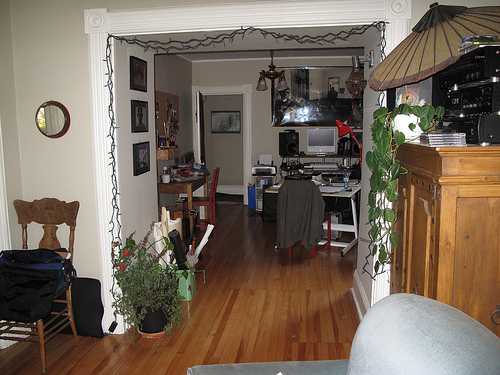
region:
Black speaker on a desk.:
[277, 129, 299, 159]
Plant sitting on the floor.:
[111, 222, 190, 337]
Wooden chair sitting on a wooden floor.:
[0, 198, 80, 372]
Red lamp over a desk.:
[335, 120, 363, 160]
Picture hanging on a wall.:
[208, 109, 242, 134]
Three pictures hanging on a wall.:
[130, 55, 150, 175]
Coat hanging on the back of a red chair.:
[270, 175, 321, 250]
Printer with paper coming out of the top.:
[250, 150, 276, 175]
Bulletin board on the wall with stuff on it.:
[152, 86, 178, 141]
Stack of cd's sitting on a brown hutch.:
[417, 131, 469, 149]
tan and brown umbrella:
[395, 4, 498, 101]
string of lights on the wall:
[108, 0, 409, 253]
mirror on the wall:
[28, 92, 99, 150]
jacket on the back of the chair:
[264, 177, 354, 267]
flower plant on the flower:
[110, 250, 202, 365]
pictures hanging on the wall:
[116, 56, 156, 191]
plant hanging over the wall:
[370, 104, 405, 287]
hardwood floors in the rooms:
[216, 248, 348, 352]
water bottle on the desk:
[333, 167, 355, 193]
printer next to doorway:
[252, 150, 280, 180]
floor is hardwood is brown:
[216, 243, 328, 342]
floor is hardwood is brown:
[246, 258, 314, 334]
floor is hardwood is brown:
[205, 293, 312, 343]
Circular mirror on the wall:
[33, 98, 69, 138]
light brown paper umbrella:
[362, 1, 497, 92]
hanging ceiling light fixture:
[255, 50, 290, 95]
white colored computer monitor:
[305, 126, 336, 156]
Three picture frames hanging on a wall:
[126, 53, 151, 176]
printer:
[250, 151, 276, 177]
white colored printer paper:
[260, 153, 271, 164]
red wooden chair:
[190, 166, 218, 226]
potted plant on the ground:
[111, 231, 177, 337]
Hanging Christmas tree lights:
[107, 17, 387, 336]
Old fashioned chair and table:
[5, 173, 106, 366]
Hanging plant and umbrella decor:
[356, 5, 496, 172]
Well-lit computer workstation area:
[269, 108, 373, 191]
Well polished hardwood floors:
[229, 265, 316, 339]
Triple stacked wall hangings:
[121, 43, 161, 185]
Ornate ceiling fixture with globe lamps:
[253, 55, 306, 135]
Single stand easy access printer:
[238, 136, 287, 248]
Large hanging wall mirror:
[255, 50, 375, 153]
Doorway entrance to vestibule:
[189, 73, 260, 225]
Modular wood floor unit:
[386, 118, 498, 261]